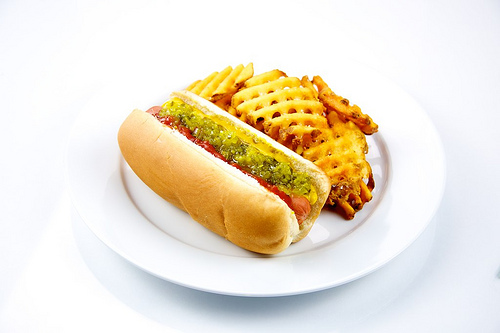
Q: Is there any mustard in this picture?
A: Yes, there is mustard.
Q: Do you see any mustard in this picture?
A: Yes, there is mustard.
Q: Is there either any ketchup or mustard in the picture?
A: Yes, there is mustard.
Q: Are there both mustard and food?
A: Yes, there are both mustard and food.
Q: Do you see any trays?
A: No, there are no trays.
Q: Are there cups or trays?
A: No, there are no trays or cups.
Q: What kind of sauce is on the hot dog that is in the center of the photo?
A: The sauce is mustard.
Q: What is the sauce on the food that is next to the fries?
A: The sauce is mustard.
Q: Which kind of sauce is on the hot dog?
A: The sauce is mustard.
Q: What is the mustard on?
A: The mustard is on the hot dog.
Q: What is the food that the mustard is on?
A: The food is a hot dog.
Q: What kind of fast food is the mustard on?
A: The mustard is on the hot dog.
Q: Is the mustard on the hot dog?
A: Yes, the mustard is on the hot dog.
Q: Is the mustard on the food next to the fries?
A: Yes, the mustard is on the hot dog.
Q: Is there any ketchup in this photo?
A: Yes, there is ketchup.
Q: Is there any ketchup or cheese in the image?
A: Yes, there is ketchup.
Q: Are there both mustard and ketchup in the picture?
A: Yes, there are both ketchup and mustard.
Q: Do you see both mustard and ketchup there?
A: Yes, there are both ketchup and mustard.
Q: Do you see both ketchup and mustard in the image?
A: Yes, there are both ketchup and mustard.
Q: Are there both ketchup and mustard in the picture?
A: Yes, there are both ketchup and mustard.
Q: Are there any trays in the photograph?
A: No, there are no trays.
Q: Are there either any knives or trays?
A: No, there are no trays or knives.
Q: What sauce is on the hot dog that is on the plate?
A: The sauce is ketchup.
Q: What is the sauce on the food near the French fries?
A: The sauce is ketchup.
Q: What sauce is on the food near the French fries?
A: The sauce is ketchup.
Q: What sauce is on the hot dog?
A: The sauce is ketchup.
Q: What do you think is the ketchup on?
A: The ketchup is on the hot dog.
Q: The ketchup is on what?
A: The ketchup is on the hot dog.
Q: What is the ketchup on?
A: The ketchup is on the hot dog.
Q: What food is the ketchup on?
A: The ketchup is on the hot dog.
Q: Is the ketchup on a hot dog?
A: Yes, the ketchup is on a hot dog.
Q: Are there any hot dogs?
A: Yes, there is a hot dog.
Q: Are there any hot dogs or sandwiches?
A: Yes, there is a hot dog.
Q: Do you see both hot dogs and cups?
A: No, there is a hot dog but no cups.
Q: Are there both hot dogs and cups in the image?
A: No, there is a hot dog but no cups.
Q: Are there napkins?
A: No, there are no napkins.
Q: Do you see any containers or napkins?
A: No, there are no napkins or containers.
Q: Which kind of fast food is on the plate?
A: The food is a hot dog.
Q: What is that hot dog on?
A: The hot dog is on the plate.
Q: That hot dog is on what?
A: The hot dog is on the plate.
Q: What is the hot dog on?
A: The hot dog is on the plate.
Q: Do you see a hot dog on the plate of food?
A: Yes, there is a hot dog on the plate.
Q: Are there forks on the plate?
A: No, there is a hot dog on the plate.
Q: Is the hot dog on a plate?
A: Yes, the hot dog is on a plate.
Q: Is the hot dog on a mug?
A: No, the hot dog is on a plate.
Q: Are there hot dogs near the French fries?
A: Yes, there is a hot dog near the French fries.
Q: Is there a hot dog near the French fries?
A: Yes, there is a hot dog near the French fries.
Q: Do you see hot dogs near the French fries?
A: Yes, there is a hot dog near the French fries.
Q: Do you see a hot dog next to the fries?
A: Yes, there is a hot dog next to the fries.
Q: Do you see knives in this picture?
A: No, there are no knives.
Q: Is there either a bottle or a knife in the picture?
A: No, there are no knives or bottles.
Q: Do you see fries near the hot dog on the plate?
A: Yes, there are fries near the hot dog.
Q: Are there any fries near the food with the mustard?
A: Yes, there are fries near the hot dog.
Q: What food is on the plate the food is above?
A: The food is fries.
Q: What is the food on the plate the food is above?
A: The food is fries.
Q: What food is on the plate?
A: The food is fries.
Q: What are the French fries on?
A: The French fries are on the plate.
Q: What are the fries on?
A: The French fries are on the plate.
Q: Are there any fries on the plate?
A: Yes, there are fries on the plate.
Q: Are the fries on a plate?
A: Yes, the fries are on a plate.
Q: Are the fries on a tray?
A: No, the fries are on a plate.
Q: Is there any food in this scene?
A: Yes, there is food.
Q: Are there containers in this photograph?
A: No, there are no containers.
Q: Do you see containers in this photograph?
A: No, there are no containers.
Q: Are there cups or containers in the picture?
A: No, there are no containers or cups.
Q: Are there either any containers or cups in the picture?
A: No, there are no containers or cups.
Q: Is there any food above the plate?
A: Yes, there is food above the plate.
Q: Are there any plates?
A: Yes, there is a plate.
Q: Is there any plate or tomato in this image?
A: Yes, there is a plate.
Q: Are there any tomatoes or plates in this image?
A: Yes, there is a plate.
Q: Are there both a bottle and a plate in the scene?
A: No, there is a plate but no bottles.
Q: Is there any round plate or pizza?
A: Yes, there is a round plate.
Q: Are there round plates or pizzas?
A: Yes, there is a round plate.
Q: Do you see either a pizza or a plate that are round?
A: Yes, the plate is round.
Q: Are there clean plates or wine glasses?
A: Yes, there is a clean plate.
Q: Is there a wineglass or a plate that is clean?
A: Yes, the plate is clean.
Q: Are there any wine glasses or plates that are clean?
A: Yes, the plate is clean.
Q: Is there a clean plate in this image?
A: Yes, there is a clean plate.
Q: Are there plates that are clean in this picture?
A: Yes, there is a clean plate.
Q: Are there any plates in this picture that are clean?
A: Yes, there is a plate that is clean.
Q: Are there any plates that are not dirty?
A: Yes, there is a clean plate.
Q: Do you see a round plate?
A: Yes, there is a round plate.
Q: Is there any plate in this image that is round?
A: Yes, there is a plate that is round.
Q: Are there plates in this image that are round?
A: Yes, there is a plate that is round.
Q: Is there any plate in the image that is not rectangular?
A: Yes, there is a round plate.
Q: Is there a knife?
A: No, there are no knives.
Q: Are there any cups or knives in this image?
A: No, there are no knives or cups.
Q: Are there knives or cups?
A: No, there are no knives or cups.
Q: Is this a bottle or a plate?
A: This is a plate.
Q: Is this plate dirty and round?
A: No, the plate is round but clean.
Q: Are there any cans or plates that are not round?
A: No, there is a plate but it is round.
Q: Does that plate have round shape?
A: Yes, the plate is round.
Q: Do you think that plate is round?
A: Yes, the plate is round.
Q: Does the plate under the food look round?
A: Yes, the plate is round.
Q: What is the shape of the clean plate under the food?
A: The plate is round.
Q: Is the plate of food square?
A: No, the plate is round.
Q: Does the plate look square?
A: No, the plate is round.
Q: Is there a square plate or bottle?
A: No, there is a plate but it is round.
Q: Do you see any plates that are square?
A: No, there is a plate but it is round.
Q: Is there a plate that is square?
A: No, there is a plate but it is round.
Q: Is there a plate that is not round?
A: No, there is a plate but it is round.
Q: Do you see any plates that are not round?
A: No, there is a plate but it is round.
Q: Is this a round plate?
A: Yes, this is a round plate.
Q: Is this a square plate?
A: No, this is a round plate.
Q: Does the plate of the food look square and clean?
A: No, the plate is clean but round.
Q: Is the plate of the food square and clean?
A: No, the plate is clean but round.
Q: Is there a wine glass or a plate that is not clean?
A: No, there is a plate but it is clean.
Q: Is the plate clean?
A: Yes, the plate is clean.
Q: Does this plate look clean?
A: Yes, the plate is clean.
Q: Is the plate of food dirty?
A: No, the plate is clean.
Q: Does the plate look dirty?
A: No, the plate is clean.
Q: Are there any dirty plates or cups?
A: No, there is a plate but it is clean.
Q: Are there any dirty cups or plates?
A: No, there is a plate but it is clean.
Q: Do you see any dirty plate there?
A: No, there is a plate but it is clean.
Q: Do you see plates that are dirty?
A: No, there is a plate but it is clean.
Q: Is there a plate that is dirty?
A: No, there is a plate but it is clean.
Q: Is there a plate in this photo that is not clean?
A: No, there is a plate but it is clean.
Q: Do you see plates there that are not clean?
A: No, there is a plate but it is clean.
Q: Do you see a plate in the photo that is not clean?
A: No, there is a plate but it is clean.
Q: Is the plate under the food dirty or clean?
A: The plate is clean.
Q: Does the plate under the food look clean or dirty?
A: The plate is clean.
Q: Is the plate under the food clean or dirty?
A: The plate is clean.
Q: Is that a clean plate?
A: Yes, that is a clean plate.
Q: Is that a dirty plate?
A: No, that is a clean plate.